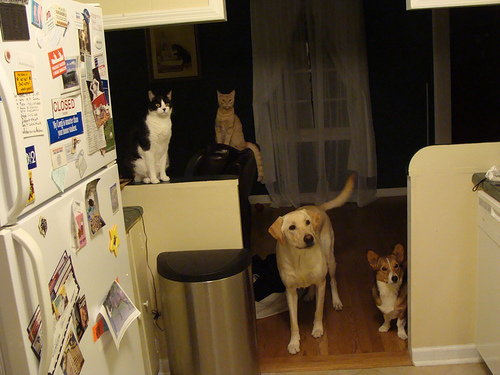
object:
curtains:
[251, 0, 375, 205]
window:
[272, 103, 318, 132]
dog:
[367, 244, 409, 338]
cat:
[123, 88, 176, 184]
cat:
[213, 89, 263, 184]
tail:
[249, 143, 264, 182]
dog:
[267, 170, 355, 355]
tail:
[322, 174, 357, 209]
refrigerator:
[0, 4, 146, 374]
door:
[1, 2, 118, 222]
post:
[19, 94, 42, 135]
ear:
[367, 248, 379, 267]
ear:
[393, 245, 406, 262]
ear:
[270, 216, 284, 241]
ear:
[302, 209, 326, 231]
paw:
[379, 324, 389, 331]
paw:
[399, 330, 408, 340]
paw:
[289, 340, 302, 354]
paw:
[310, 324, 325, 337]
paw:
[334, 300, 343, 308]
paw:
[150, 178, 161, 185]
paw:
[162, 176, 173, 183]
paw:
[144, 179, 150, 183]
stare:
[381, 265, 400, 274]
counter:
[122, 168, 255, 358]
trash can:
[158, 248, 258, 373]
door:
[0, 166, 140, 373]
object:
[72, 205, 86, 249]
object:
[76, 214, 93, 254]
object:
[93, 278, 139, 353]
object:
[47, 99, 84, 141]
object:
[45, 48, 68, 77]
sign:
[51, 99, 76, 119]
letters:
[52, 99, 58, 112]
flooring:
[251, 194, 406, 373]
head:
[375, 253, 408, 286]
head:
[281, 213, 319, 252]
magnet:
[16, 71, 34, 92]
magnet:
[32, 3, 41, 27]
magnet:
[39, 218, 46, 234]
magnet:
[107, 229, 124, 252]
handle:
[0, 66, 33, 222]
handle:
[8, 229, 55, 373]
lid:
[156, 249, 252, 284]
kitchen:
[122, 144, 499, 373]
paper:
[108, 178, 119, 217]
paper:
[54, 165, 67, 192]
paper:
[89, 72, 109, 128]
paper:
[59, 335, 84, 374]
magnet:
[6, 51, 12, 62]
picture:
[144, 24, 201, 84]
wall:
[386, 1, 424, 153]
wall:
[409, 144, 471, 365]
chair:
[225, 145, 258, 192]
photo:
[59, 61, 80, 87]